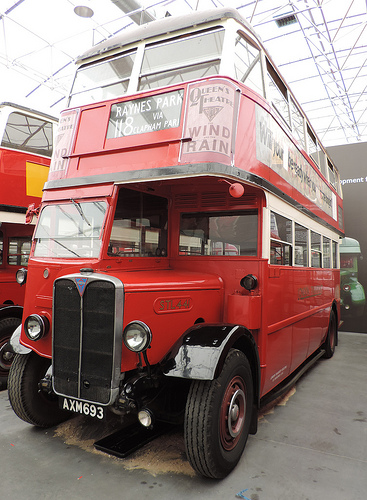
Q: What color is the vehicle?
A: Red.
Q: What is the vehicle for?
A: Transporting passengers.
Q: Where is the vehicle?
A: In a garage.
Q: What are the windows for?
A: To look out.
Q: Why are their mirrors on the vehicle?
A: To see around the vehicle.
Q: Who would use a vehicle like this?
A: Tourists.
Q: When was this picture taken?
A: Daytime.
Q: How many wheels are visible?
A: Three.